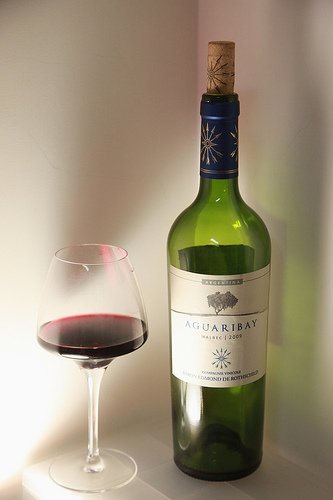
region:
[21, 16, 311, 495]
close-up of a libation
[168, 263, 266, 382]
label on a wine bottle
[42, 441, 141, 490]
base of a wine glass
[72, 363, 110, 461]
stem of a wine glass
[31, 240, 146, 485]
glass of red wine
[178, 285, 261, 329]
logo and name of the manufacturer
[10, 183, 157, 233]
wall behind the display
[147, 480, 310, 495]
surface where the bottle and glass are set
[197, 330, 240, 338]
printed notice of the wine's vintage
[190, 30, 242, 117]
cork in the top of the bottle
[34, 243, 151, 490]
a glass of red whine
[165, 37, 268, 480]
an empty bottle of wine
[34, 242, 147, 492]
an almost empty glass of wine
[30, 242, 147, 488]
a wine glass with a small crack in it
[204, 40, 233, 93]
a wine cork with a sun printed on it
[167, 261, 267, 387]
label of a wine bottle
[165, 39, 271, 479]
a green bottle of wine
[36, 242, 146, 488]
red whine in a wine glass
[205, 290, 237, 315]
picture of a tree on a wine bottle lable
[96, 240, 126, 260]
lipstick on a wine glass rim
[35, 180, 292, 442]
a picture of wine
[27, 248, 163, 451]
this wine is red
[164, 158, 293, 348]
a green wine bottle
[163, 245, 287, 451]
the wine bottle is green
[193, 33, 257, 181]
a cork on the wine bottle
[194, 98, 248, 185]
a blue label on the wine bottle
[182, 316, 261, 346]
the name of the wine brand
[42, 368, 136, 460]
the stem of the wine glass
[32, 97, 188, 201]
a white background for this picture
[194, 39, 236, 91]
a cork in a bottle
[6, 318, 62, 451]
light shining on the wall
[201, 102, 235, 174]
a blue label on the bottle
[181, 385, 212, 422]
light reflecting on the bottle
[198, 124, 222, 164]
a gold star on the lable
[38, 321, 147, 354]
red wine in a glass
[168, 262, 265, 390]
a blue and white bottle lable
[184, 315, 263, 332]
blue lettering on the label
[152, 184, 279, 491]
a bright green wine bottle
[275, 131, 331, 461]
a plain white wall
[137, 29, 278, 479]
the bottle is green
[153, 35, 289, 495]
the bottle is glass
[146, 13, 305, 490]
the bottle is empty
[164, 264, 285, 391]
the label on the bottle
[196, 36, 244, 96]
the cork in the bottle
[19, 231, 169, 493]
the glass beside the bottle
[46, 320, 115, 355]
wine in the glass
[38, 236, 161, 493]
the glass is glass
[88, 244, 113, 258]
lipstick on the glass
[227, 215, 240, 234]
the reflection on the bottle